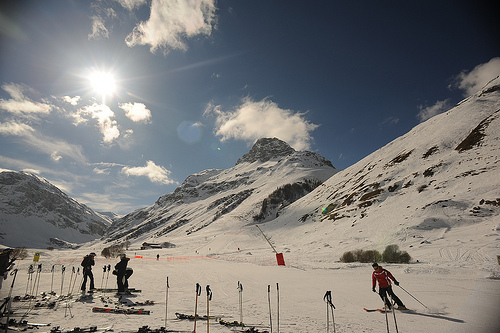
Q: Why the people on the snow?
A: For skiing.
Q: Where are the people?
A: On the snow.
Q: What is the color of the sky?
A: Blue and sky.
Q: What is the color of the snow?
A: White.